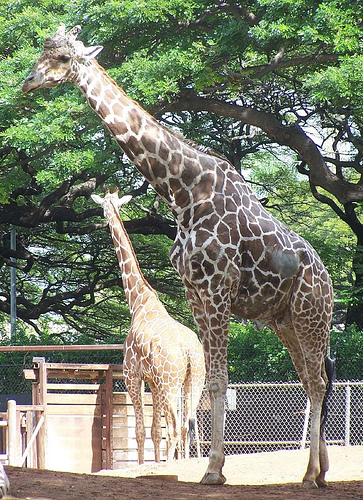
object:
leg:
[200, 308, 229, 488]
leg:
[191, 308, 227, 487]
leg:
[275, 321, 331, 488]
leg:
[296, 323, 327, 491]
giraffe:
[89, 189, 206, 464]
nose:
[22, 74, 36, 92]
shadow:
[10, 465, 361, 499]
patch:
[270, 243, 299, 278]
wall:
[295, 83, 363, 126]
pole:
[9, 223, 17, 345]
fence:
[1, 346, 361, 456]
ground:
[242, 430, 343, 474]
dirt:
[107, 488, 313, 500]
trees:
[0, 9, 356, 169]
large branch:
[1, 280, 126, 320]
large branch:
[1, 170, 104, 233]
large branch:
[247, 96, 363, 208]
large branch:
[127, 208, 178, 241]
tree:
[0, 0, 361, 375]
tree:
[1, 0, 233, 207]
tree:
[219, 2, 361, 166]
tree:
[226, 324, 298, 382]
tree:
[328, 321, 361, 383]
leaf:
[333, 50, 352, 65]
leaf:
[239, 325, 272, 362]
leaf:
[54, 119, 97, 160]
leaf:
[12, 44, 28, 58]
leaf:
[180, 7, 196, 22]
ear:
[66, 25, 82, 40]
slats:
[0, 356, 177, 472]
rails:
[344, 381, 351, 475]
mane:
[92, 52, 228, 160]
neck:
[107, 212, 158, 306]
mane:
[111, 200, 160, 304]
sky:
[305, 123, 349, 158]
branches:
[242, 57, 316, 97]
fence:
[230, 377, 363, 454]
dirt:
[86, 473, 103, 500]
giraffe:
[20, 21, 336, 492]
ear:
[91, 193, 105, 204]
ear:
[120, 195, 133, 205]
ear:
[84, 45, 104, 57]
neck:
[79, 72, 207, 233]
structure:
[0, 350, 192, 477]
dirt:
[2, 469, 93, 499]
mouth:
[21, 76, 39, 96]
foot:
[137, 458, 146, 466]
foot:
[299, 475, 317, 491]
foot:
[315, 472, 329, 490]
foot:
[198, 469, 226, 485]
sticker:
[198, 388, 236, 410]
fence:
[183, 379, 361, 459]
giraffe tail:
[319, 322, 336, 443]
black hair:
[320, 355, 337, 441]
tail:
[189, 357, 195, 441]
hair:
[188, 417, 195, 445]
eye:
[57, 53, 71, 63]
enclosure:
[5, 380, 360, 497]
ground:
[0, 445, 359, 498]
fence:
[12, 350, 198, 466]